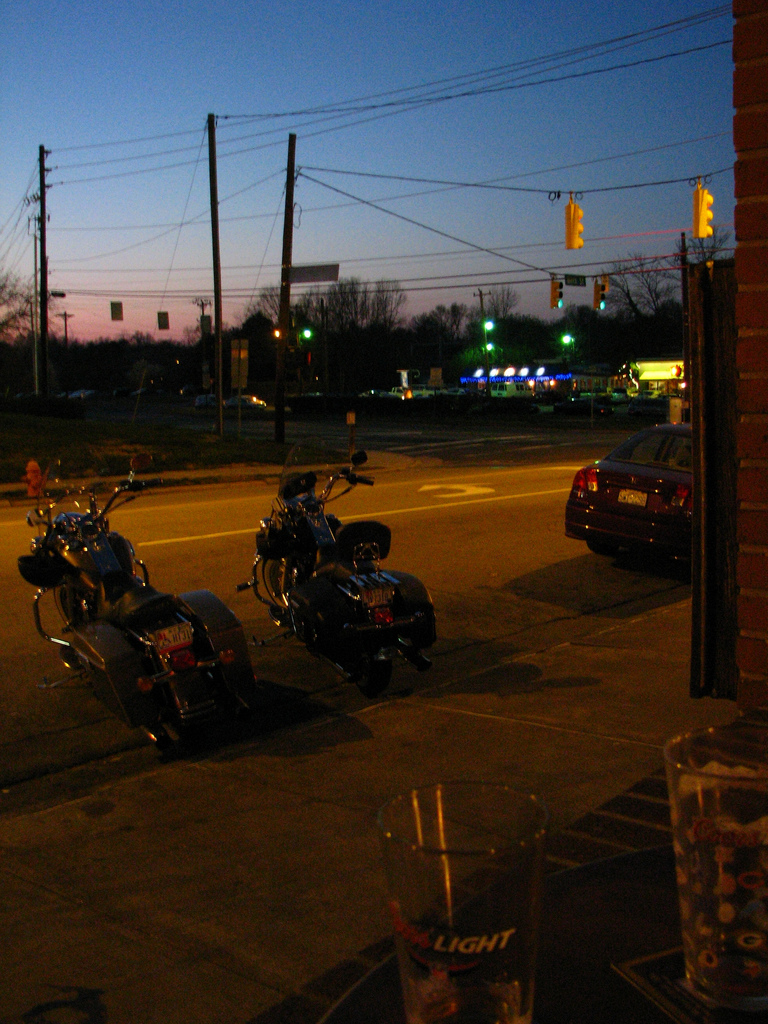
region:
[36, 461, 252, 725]
parked bike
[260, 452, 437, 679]
bike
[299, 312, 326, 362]
green light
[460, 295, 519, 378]
green signal light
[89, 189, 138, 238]
white clouds in blue sky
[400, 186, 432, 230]
white clouds in the blue sky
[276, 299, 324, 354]
green light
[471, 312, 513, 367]
green lights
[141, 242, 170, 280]
white clouds in the blue sky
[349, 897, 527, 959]
coors light logo on a glass with ice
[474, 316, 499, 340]
green light on traffic signal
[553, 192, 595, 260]
back side of yellow traffic signal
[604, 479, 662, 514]
white license plate on back of car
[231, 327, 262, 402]
back side of metal white street signs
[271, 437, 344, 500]
clear windshield on front of motorcycle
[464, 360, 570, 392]
blue neon lights on distant building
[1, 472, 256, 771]
bike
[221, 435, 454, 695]
bike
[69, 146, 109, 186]
white clouds in blue sky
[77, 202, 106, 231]
white clouds in blue sky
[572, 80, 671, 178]
white clouds in blue sky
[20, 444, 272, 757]
The motorcycle on the right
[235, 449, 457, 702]
The motorcycle on the left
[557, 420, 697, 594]
The car parked next to the motorcycles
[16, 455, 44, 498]
The fire hydrant accross the street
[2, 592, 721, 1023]
The sidewalk in front of the table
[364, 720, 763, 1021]
The empty beer glasses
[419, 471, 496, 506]
The left turn arrow on the street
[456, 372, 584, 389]
The strand of blue lights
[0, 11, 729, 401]
wires suspended from telephone poles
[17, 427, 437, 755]
two parked motorcycles side by side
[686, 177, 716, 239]
back of hanging traffic light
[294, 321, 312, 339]
light in the dark night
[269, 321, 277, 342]
light in the dark night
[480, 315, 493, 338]
light in the dark night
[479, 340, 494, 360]
light in the dark night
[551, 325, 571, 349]
light in the dark night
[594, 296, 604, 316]
light in the dark night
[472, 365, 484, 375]
light in the dark night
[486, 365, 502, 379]
light in the dark night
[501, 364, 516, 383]
light in the dark night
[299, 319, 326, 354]
bright light in the dark night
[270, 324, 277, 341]
bright light in the dark night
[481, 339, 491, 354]
bright light in the dark night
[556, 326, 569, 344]
bright light in the dark night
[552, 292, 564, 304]
bright light in the dark night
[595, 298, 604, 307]
bright light in the dark night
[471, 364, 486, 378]
bright light in the dark night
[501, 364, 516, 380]
bright light in the dark night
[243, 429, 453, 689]
Motorcycle on the curb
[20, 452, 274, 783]
Motorcycle on the curb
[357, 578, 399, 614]
license on the motorcycle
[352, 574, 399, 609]
license on the motorcycle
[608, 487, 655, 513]
license on the car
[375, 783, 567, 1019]
glass on the table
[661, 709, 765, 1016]
glass on the table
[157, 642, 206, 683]
red light on the motorcycle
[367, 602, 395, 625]
red light on the motorcycle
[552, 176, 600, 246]
a traffic light on the line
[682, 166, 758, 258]
a traffic light on the line